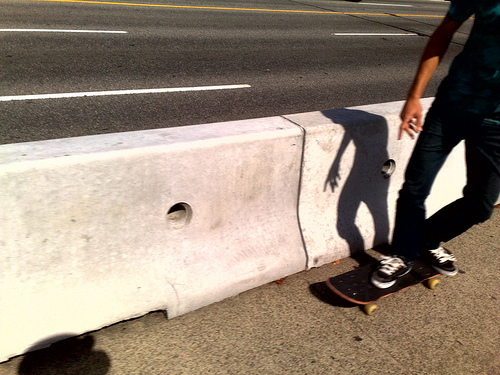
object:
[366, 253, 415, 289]
shoe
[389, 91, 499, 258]
jeans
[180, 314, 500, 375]
sidewalk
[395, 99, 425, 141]
hand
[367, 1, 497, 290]
skater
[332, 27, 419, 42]
line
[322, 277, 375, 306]
tip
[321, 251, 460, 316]
board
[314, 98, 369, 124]
head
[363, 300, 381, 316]
wheel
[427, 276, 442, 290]
wheel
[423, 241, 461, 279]
sneakers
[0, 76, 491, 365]
barrier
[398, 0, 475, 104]
arm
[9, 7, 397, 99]
ground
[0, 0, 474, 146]
street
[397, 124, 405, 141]
finger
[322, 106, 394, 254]
shadow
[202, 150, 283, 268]
wall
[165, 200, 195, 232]
hole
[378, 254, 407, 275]
laces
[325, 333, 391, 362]
flecks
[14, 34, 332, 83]
lane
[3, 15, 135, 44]
lines